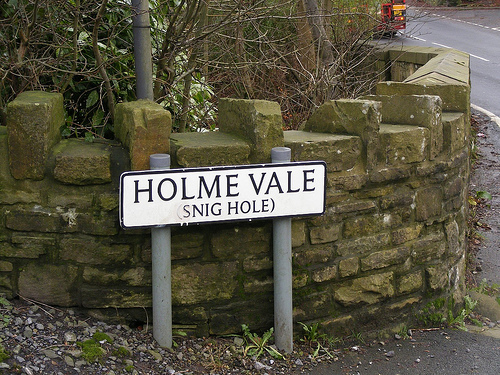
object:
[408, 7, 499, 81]
lines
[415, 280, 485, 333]
grass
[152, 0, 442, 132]
tree branches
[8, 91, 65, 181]
rocks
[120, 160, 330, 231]
steel plate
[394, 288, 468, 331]
brick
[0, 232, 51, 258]
brick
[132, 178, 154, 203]
h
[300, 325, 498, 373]
floor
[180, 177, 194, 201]
l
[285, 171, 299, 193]
l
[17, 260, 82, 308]
brick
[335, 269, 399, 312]
brick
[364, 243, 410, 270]
brick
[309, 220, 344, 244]
brick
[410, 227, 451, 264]
brick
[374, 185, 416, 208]
brick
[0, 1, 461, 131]
branches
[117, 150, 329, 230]
plate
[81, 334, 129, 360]
moss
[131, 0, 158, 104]
pipe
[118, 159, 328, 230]
white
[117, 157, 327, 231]
sign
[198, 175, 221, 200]
letter m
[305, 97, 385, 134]
brick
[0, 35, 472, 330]
container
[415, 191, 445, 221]
brick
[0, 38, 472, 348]
wall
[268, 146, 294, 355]
pole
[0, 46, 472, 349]
brick walls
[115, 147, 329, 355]
signpost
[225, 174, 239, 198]
letter e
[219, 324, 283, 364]
weeds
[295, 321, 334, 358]
weeds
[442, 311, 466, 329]
weeds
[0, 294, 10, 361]
weeds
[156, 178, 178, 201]
letter o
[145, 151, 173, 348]
pole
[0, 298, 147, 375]
pebble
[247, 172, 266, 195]
letter v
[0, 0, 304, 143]
tree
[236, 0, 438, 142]
tree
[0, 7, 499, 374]
ground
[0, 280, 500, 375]
rock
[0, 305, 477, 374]
debris